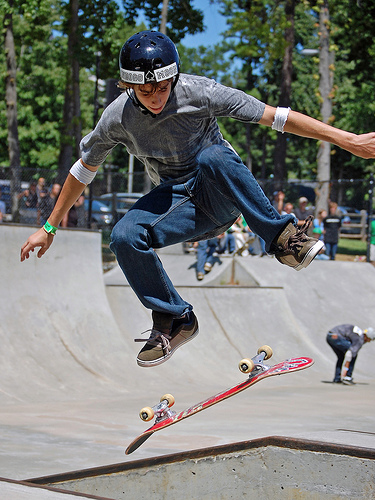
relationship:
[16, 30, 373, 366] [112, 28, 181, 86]
boy wearing a helmet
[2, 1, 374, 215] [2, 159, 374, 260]
trees outside of fence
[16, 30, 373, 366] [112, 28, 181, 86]
boy wearing protective helmet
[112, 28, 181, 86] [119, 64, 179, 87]
helmet has trim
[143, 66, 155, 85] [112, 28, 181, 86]
spade on front of helmet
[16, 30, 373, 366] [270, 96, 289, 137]
boy wearing band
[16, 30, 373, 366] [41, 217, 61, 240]
boy wearing band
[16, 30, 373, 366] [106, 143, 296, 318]
boy wearing pants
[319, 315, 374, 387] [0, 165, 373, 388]
person in background